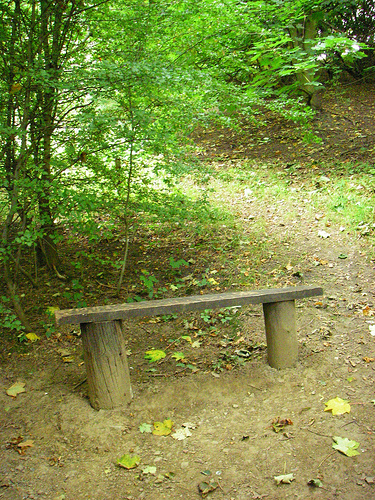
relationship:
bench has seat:
[54, 285, 325, 409] [54, 283, 325, 324]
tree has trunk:
[2, 0, 355, 347] [13, 7, 71, 291]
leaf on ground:
[115, 451, 142, 467] [4, 67, 374, 499]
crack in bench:
[97, 356, 114, 406] [54, 285, 325, 409]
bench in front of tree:
[54, 285, 325, 409] [2, 0, 355, 347]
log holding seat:
[83, 319, 132, 416] [54, 283, 325, 324]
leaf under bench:
[115, 451, 142, 467] [54, 285, 325, 409]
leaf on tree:
[167, 258, 183, 271] [2, 0, 355, 347]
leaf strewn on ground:
[115, 451, 142, 467] [4, 67, 374, 499]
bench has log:
[54, 285, 325, 409] [261, 293, 299, 371]